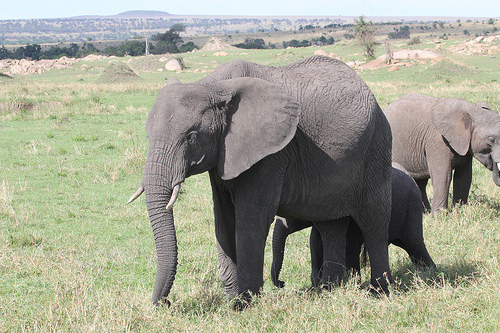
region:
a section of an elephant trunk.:
[123, 170, 183, 275]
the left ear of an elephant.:
[211, 71, 307, 193]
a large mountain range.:
[0, 23, 496, 47]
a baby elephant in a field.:
[363, 91, 498, 210]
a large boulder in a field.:
[158, 48, 184, 81]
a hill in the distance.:
[211, 25, 257, 72]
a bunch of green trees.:
[139, 16, 189, 62]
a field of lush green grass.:
[6, 89, 496, 331]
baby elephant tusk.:
[126, 177, 191, 212]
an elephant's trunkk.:
[266, 211, 298, 321]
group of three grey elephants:
[131, 56, 498, 307]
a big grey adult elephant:
[130, 55, 394, 303]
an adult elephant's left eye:
[182, 126, 199, 146]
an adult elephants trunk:
[141, 166, 178, 303]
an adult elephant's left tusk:
[164, 183, 182, 213]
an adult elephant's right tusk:
[127, 182, 145, 204]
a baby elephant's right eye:
[482, 132, 497, 147]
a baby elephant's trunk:
[270, 216, 288, 287]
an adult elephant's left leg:
[350, 192, 398, 289]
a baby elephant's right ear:
[425, 99, 473, 159]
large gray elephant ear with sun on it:
[216, 74, 306, 184]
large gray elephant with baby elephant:
[112, 52, 442, 318]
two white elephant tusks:
[123, 170, 183, 215]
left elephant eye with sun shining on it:
[181, 123, 202, 154]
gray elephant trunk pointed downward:
[126, 131, 188, 308]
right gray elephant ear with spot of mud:
[428, 91, 475, 172]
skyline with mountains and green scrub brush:
[10, 4, 499, 51]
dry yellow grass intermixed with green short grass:
[18, 278, 139, 327]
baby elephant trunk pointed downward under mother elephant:
[264, 208, 300, 291]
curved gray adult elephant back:
[181, 43, 363, 95]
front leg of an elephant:
[252, 232, 257, 260]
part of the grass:
[354, 297, 364, 311]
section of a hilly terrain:
[95, 19, 125, 27]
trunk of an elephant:
[167, 237, 173, 263]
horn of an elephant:
[166, 165, 183, 228]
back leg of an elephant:
[378, 197, 380, 204]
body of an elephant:
[339, 196, 342, 197]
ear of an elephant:
[243, 147, 253, 152]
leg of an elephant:
[241, 234, 246, 249]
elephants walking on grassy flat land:
[76, 37, 492, 307]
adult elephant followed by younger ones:
[123, 55, 488, 315]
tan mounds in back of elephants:
[10, 15, 485, 80]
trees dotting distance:
[10, 5, 315, 35]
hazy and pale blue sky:
[25, 0, 410, 15]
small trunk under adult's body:
[245, 200, 300, 300]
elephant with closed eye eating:
[385, 65, 495, 220]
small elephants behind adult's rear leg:
[120, 45, 435, 310]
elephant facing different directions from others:
[365, 65, 495, 225]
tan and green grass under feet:
[42, 180, 482, 330]